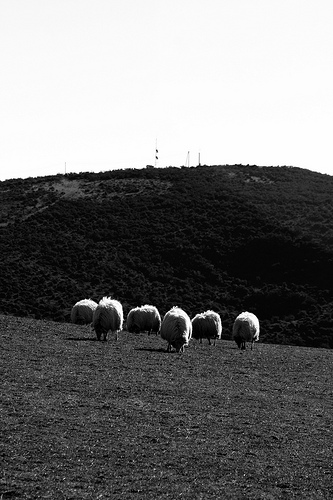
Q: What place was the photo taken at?
A: It was taken at the field.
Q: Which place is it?
A: It is a field.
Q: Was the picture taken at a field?
A: Yes, it was taken in a field.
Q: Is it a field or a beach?
A: It is a field.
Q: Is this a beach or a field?
A: It is a field.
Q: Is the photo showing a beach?
A: No, the picture is showing a field.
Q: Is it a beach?
A: No, it is a field.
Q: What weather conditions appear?
A: It is cloudless.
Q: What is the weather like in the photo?
A: It is cloudless.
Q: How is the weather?
A: It is cloudless.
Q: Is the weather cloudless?
A: Yes, it is cloudless.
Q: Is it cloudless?
A: Yes, it is cloudless.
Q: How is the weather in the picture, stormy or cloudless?
A: It is cloudless.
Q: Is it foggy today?
A: No, it is cloudless.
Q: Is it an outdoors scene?
A: Yes, it is outdoors.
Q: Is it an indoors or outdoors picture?
A: It is outdoors.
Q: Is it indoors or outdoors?
A: It is outdoors.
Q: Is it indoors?
A: No, it is outdoors.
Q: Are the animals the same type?
A: Yes, all the animals are sheep.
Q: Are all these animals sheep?
A: Yes, all the animals are sheep.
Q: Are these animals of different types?
A: No, all the animals are sheep.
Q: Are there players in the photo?
A: No, there are no players.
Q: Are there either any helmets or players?
A: No, there are no players or helmets.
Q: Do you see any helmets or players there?
A: No, there are no players or helmets.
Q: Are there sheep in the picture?
A: Yes, there is a sheep.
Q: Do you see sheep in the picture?
A: Yes, there is a sheep.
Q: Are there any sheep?
A: Yes, there is a sheep.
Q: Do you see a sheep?
A: Yes, there is a sheep.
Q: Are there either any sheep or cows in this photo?
A: Yes, there is a sheep.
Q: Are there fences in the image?
A: No, there are no fences.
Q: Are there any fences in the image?
A: No, there are no fences.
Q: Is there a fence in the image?
A: No, there are no fences.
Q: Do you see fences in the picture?
A: No, there are no fences.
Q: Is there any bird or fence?
A: No, there are no fences or birds.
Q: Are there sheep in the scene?
A: Yes, there is a sheep.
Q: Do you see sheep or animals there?
A: Yes, there is a sheep.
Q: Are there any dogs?
A: No, there are no dogs.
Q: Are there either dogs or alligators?
A: No, there are no dogs or alligators.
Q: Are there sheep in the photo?
A: Yes, there is a sheep.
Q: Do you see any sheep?
A: Yes, there is a sheep.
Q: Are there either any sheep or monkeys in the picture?
A: Yes, there is a sheep.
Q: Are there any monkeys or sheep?
A: Yes, there is a sheep.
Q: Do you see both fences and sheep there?
A: No, there is a sheep but no fences.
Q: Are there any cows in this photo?
A: No, there are no cows.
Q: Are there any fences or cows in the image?
A: No, there are no cows or fences.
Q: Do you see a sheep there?
A: Yes, there is a sheep.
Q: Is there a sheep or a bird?
A: Yes, there is a sheep.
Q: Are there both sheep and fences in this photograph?
A: No, there is a sheep but no fences.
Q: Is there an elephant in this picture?
A: No, there are no elephants.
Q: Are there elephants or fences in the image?
A: No, there are no elephants or fences.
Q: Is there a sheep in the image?
A: Yes, there is a sheep.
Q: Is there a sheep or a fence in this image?
A: Yes, there is a sheep.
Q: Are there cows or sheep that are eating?
A: Yes, the sheep is eating.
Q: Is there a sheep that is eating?
A: Yes, there is a sheep that is eating.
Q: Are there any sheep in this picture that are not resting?
A: Yes, there is a sheep that is eating.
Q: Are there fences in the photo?
A: No, there are no fences.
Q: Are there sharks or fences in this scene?
A: No, there are no fences or sharks.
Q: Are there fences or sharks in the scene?
A: No, there are no fences or sharks.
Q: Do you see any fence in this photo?
A: No, there are no fences.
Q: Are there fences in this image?
A: No, there are no fences.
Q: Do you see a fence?
A: No, there are no fences.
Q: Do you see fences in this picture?
A: No, there are no fences.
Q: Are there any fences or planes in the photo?
A: No, there are no fences or planes.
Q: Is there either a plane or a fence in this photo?
A: No, there are no fences or airplanes.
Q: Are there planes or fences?
A: No, there are no fences or planes.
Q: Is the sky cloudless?
A: Yes, the sky is cloudless.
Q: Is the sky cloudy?
A: No, the sky is cloudless.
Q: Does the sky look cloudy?
A: No, the sky is cloudless.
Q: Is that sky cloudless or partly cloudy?
A: The sky is cloudless.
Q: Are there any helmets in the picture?
A: No, there are no helmets.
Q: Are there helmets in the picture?
A: No, there are no helmets.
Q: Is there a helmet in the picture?
A: No, there are no helmets.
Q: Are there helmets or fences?
A: No, there are no helmets or fences.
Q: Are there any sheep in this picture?
A: Yes, there is a sheep.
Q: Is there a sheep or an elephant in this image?
A: Yes, there is a sheep.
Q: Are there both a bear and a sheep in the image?
A: No, there is a sheep but no bears.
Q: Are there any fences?
A: No, there are no fences.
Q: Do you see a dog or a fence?
A: No, there are no fences or dogs.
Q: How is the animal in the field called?
A: The animal is a sheep.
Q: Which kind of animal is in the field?
A: The animal is a sheep.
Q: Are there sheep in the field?
A: Yes, there is a sheep in the field.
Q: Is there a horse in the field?
A: No, there is a sheep in the field.